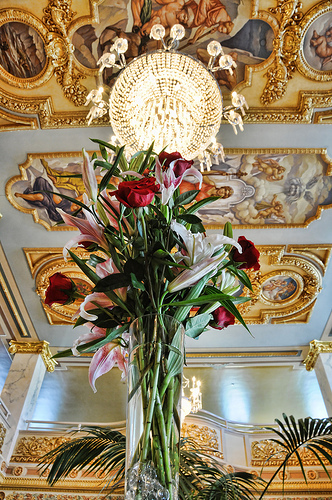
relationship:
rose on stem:
[105, 173, 166, 213] [135, 208, 158, 300]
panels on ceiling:
[3, 3, 326, 328] [3, 5, 323, 348]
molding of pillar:
[10, 338, 57, 372] [0, 336, 58, 488]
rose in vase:
[105, 173, 166, 213] [127, 312, 187, 499]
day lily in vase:
[159, 150, 215, 210] [127, 312, 187, 499]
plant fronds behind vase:
[27, 414, 311, 500] [127, 312, 187, 499]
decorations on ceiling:
[244, 8, 308, 119] [3, 5, 323, 348]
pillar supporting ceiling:
[0, 336, 58, 488] [3, 5, 323, 348]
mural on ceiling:
[43, 163, 316, 232] [3, 5, 323, 348]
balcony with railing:
[14, 417, 327, 494] [27, 417, 130, 428]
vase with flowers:
[127, 312, 187, 499] [37, 137, 258, 359]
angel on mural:
[251, 153, 287, 187] [43, 163, 316, 232]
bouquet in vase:
[37, 137, 258, 359] [127, 312, 187, 499]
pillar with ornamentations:
[0, 336, 58, 488] [10, 338, 57, 372]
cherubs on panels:
[248, 157, 292, 224] [0, 0, 332, 334]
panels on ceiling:
[0, 0, 332, 334] [3, 5, 323, 348]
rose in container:
[105, 173, 166, 213] [127, 312, 187, 499]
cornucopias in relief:
[40, 3, 93, 115] [10, 5, 331, 126]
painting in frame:
[3, 24, 48, 79] [27, 74, 52, 88]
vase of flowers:
[127, 312, 187, 499] [37, 137, 258, 359]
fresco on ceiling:
[3, 3, 326, 328] [3, 5, 323, 348]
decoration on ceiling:
[3, 3, 326, 328] [3, 5, 323, 348]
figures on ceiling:
[248, 157, 292, 224] [3, 5, 323, 348]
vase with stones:
[127, 312, 187, 499] [127, 456, 169, 494]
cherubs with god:
[248, 157, 292, 224] [282, 174, 320, 214]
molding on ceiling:
[10, 338, 57, 372] [3, 5, 323, 348]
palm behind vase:
[27, 414, 311, 500] [127, 312, 187, 499]